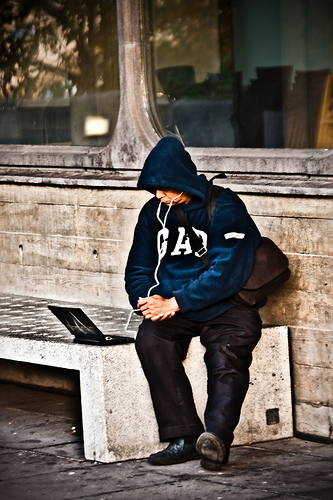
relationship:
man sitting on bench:
[123, 137, 289, 471] [4, 285, 298, 484]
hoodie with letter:
[123, 136, 266, 318] [154, 225, 173, 260]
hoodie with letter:
[123, 136, 266, 318] [170, 222, 194, 257]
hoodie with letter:
[123, 136, 266, 318] [191, 223, 209, 256]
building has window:
[0, 1, 331, 444] [141, 2, 327, 158]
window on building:
[0, 0, 120, 149] [0, 1, 331, 444]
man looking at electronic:
[113, 133, 294, 470] [45, 301, 134, 346]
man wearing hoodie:
[123, 137, 289, 471] [131, 157, 213, 210]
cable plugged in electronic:
[124, 206, 177, 329] [47, 303, 135, 346]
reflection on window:
[6, 9, 114, 99] [3, 1, 331, 145]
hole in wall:
[92, 250, 97, 257] [0, 177, 331, 437]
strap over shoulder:
[169, 207, 225, 264] [205, 177, 254, 222]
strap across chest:
[167, 206, 210, 269] [141, 204, 235, 261]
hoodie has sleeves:
[123, 136, 259, 324] [121, 199, 249, 307]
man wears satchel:
[123, 137, 289, 471] [192, 235, 297, 312]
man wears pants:
[123, 137, 289, 471] [134, 284, 260, 373]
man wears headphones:
[123, 137, 289, 471] [120, 187, 186, 336]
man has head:
[123, 137, 289, 471] [126, 133, 209, 222]